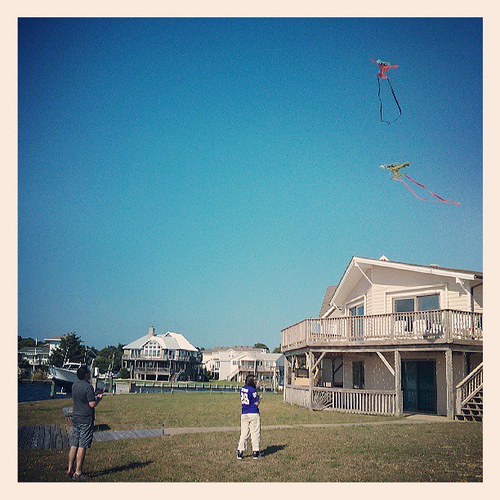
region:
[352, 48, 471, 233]
colorful kites in the sky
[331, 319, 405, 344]
deck on the house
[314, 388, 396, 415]
wooden fence on the house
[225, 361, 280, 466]
woman wearing a jersey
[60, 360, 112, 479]
guy flying the kites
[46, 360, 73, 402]
boat in the water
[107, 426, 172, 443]
wooden pathway on the ground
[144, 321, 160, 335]
chimney on top of the house roof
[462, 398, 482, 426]
stairs on the house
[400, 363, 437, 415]
sliding door on the house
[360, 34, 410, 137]
kite flying over house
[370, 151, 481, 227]
kite flying over house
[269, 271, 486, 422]
white house on right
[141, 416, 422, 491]
green grass growing on ground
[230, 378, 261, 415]
blue shirt on woman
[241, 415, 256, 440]
tan pants on woman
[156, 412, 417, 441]
sidewalk going through yard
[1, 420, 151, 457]
wooden dock on left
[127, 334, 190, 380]
tall house across canal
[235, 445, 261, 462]
blue sneakers on woman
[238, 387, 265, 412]
the shirt is blue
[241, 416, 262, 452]
the pants are brown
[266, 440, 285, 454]
shadow is on the ground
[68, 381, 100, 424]
the shirt is grey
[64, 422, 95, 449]
the shorts are grey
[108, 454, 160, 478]
shadow is on the ground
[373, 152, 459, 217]
kite is in the air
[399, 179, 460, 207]
the strings are purple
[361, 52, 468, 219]
two kites are in the air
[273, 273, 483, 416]
the structure is wooden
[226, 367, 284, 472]
Woman wearing blue shirt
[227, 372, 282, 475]
Woman wearing blue shirt and gray pants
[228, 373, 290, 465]
Women facing facing away from camera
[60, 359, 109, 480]
Man wearing gray shirt and shorts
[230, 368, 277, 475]
Woman wearing purple jersey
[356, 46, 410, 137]
Red kite flying in air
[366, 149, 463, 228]
Yellow kite flying in the air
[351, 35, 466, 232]
Two kites flying in the sky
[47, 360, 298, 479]
Two people looking up at the sky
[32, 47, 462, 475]
Two people flying kites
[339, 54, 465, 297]
two kites in the sky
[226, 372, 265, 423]
a blue shirt with white numbers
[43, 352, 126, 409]
a white and black boat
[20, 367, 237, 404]
a small body of water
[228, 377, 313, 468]
blue shirt and white pants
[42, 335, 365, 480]
two people flying kites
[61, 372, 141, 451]
a gray shirt and gray shorts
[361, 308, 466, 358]
white chairs on the deck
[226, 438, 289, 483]
black and white shoes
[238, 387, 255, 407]
white numbers on shirt